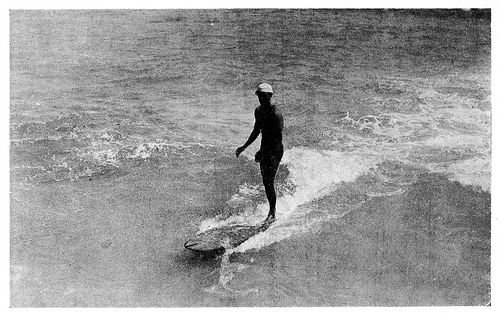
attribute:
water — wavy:
[15, 13, 393, 292]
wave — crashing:
[104, 140, 387, 251]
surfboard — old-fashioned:
[184, 221, 268, 258]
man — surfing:
[233, 81, 285, 227]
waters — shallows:
[15, 13, 401, 291]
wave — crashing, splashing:
[134, 140, 392, 249]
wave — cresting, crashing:
[186, 143, 499, 278]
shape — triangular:
[294, 153, 484, 309]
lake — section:
[18, 10, 485, 309]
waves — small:
[270, 78, 495, 211]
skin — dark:
[240, 94, 280, 219]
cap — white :
[256, 83, 274, 95]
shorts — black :
[258, 142, 284, 168]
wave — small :
[21, 76, 488, 240]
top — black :
[255, 102, 284, 155]